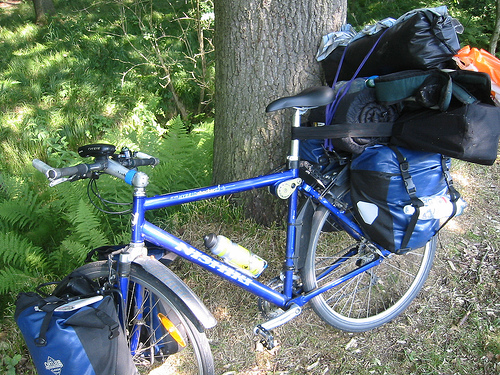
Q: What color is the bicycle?
A: Blue.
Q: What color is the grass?
A: Green.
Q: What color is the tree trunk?
A: Brown.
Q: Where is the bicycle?
A: Next to the tree.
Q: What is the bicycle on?
A: Dirt.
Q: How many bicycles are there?
A: One.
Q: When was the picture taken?
A: Daytime.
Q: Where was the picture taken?
A: On a biking path in a forest.